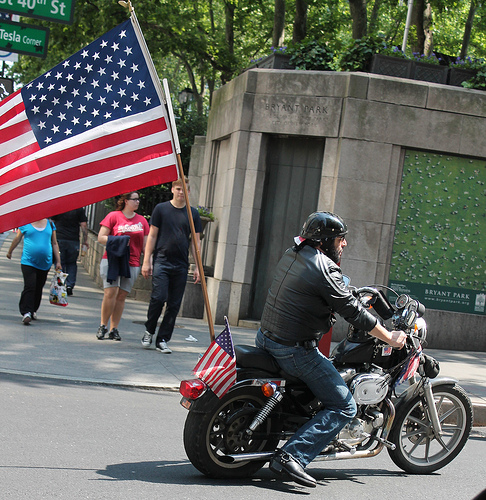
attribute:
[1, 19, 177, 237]
flag — small, american, large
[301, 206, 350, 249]
helmet — black, hard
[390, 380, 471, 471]
wheel — black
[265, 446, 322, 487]
boot — leather, black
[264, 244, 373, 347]
shirt — black, leather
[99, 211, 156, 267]
shirt — red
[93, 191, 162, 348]
woman — walking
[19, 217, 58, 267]
shirt — blue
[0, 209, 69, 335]
person — pregnant, walking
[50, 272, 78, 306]
bag — plastic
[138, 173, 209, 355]
man — walking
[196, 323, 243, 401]
flag — small, american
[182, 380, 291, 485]
wheel — black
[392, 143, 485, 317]
picture — green, large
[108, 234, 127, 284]
jacket — dark blue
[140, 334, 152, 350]
shoe — white, black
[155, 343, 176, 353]
shoe — white, black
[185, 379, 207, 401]
light — red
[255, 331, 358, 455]
jeans — blue